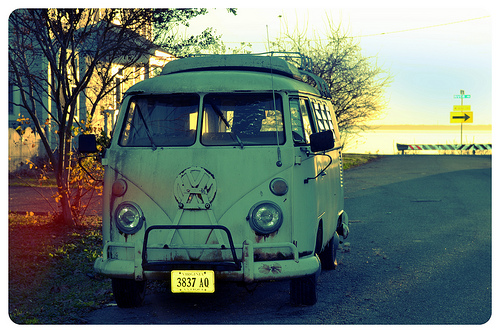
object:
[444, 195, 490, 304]
part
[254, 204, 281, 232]
light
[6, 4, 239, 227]
tree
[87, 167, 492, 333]
black pavement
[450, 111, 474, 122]
sign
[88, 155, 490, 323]
pavement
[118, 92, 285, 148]
front windows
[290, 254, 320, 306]
front tires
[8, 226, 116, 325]
bed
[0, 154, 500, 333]
ground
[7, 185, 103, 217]
walkway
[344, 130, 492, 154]
water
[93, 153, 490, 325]
road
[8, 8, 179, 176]
house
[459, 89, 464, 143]
post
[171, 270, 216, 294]
license plate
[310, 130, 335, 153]
mirror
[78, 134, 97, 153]
mirror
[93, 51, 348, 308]
bus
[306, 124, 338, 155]
mirror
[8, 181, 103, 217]
sidewalk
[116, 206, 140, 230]
headlight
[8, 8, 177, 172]
home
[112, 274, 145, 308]
tire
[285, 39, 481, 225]
background